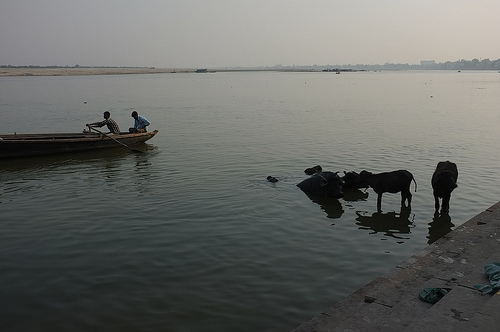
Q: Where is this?
A: This is at the lake.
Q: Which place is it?
A: It is a lake.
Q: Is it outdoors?
A: Yes, it is outdoors.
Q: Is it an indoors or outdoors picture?
A: It is outdoors.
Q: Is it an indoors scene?
A: No, it is outdoors.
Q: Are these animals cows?
A: Yes, all the animals are cows.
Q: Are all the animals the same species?
A: Yes, all the animals are cows.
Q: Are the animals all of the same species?
A: Yes, all the animals are cows.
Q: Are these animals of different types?
A: No, all the animals are cows.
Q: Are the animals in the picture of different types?
A: No, all the animals are cows.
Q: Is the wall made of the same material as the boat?
A: No, the wall is made of cement and the boat is made of wood.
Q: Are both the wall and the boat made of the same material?
A: No, the wall is made of cement and the boat is made of wood.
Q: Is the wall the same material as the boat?
A: No, the wall is made of cement and the boat is made of wood.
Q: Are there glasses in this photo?
A: No, there are no glasses.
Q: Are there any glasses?
A: No, there are no glasses.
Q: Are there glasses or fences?
A: No, there are no glasses or fences.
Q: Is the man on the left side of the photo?
A: Yes, the man is on the left of the image.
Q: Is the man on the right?
A: No, the man is on the left of the image.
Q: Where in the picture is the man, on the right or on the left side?
A: The man is on the left of the image.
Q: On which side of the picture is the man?
A: The man is on the left of the image.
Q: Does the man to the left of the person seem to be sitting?
A: Yes, the man is sitting.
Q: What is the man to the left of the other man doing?
A: The man is sitting.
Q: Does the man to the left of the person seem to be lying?
A: No, the man is sitting.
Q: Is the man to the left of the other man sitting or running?
A: The man is sitting.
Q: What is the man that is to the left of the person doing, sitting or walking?
A: The man is sitting.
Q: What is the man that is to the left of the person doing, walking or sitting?
A: The man is sitting.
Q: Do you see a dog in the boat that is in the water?
A: No, there is a man in the boat.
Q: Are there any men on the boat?
A: Yes, there is a man on the boat.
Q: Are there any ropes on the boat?
A: No, there is a man on the boat.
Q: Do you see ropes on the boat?
A: No, there is a man on the boat.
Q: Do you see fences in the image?
A: No, there are no fences.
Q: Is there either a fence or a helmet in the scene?
A: No, there are no fences or helmets.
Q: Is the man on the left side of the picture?
A: Yes, the man is on the left of the image.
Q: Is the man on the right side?
A: No, the man is on the left of the image.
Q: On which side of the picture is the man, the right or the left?
A: The man is on the left of the image.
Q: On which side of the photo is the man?
A: The man is on the left of the image.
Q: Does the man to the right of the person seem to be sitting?
A: Yes, the man is sitting.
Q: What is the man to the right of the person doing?
A: The man is sitting.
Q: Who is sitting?
A: The man is sitting.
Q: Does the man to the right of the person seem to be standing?
A: No, the man is sitting.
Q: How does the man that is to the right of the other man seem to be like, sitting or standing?
A: The man is sitting.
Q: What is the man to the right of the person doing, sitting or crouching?
A: The man is sitting.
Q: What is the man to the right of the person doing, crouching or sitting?
A: The man is sitting.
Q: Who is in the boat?
A: The man is in the boat.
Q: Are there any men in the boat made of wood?
A: Yes, there is a man in the boat.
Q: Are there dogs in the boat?
A: No, there is a man in the boat.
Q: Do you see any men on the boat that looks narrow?
A: Yes, there is a man on the boat.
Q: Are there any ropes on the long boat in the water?
A: No, there is a man on the boat.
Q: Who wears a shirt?
A: The man wears a shirt.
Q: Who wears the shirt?
A: The man wears a shirt.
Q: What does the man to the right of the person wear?
A: The man wears a shirt.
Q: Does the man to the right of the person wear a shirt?
A: Yes, the man wears a shirt.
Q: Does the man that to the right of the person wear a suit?
A: No, the man wears a shirt.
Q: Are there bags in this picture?
A: No, there are no bags.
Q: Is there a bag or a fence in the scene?
A: No, there are no bags or fences.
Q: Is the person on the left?
A: Yes, the person is on the left of the image.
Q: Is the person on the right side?
A: No, the person is on the left of the image.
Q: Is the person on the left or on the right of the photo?
A: The person is on the left of the image.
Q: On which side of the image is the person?
A: The person is on the left of the image.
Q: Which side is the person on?
A: The person is on the left of the image.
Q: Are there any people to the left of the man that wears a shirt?
A: Yes, there is a person to the left of the man.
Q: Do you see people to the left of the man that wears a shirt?
A: Yes, there is a person to the left of the man.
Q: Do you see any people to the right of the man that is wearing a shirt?
A: No, the person is to the left of the man.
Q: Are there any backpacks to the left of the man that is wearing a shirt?
A: No, there is a person to the left of the man.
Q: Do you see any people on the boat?
A: Yes, there is a person on the boat.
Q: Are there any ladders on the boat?
A: No, there is a person on the boat.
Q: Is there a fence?
A: No, there are no fences.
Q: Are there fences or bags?
A: No, there are no fences or bags.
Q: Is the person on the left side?
A: Yes, the person is on the left of the image.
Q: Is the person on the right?
A: No, the person is on the left of the image.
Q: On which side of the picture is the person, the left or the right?
A: The person is on the left of the image.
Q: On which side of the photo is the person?
A: The person is on the left of the image.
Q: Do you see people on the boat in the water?
A: Yes, there is a person on the boat.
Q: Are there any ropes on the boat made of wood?
A: No, there is a person on the boat.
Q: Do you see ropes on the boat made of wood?
A: No, there is a person on the boat.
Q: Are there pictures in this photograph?
A: No, there are no pictures.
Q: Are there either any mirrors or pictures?
A: No, there are no pictures or mirrors.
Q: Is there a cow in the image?
A: Yes, there is a cow.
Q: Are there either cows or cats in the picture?
A: Yes, there is a cow.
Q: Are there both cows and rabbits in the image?
A: No, there is a cow but no rabbits.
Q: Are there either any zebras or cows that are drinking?
A: Yes, the cow is drinking.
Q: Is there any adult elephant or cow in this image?
A: Yes, there is an adult cow.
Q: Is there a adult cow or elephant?
A: Yes, there is an adult cow.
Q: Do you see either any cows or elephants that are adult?
A: Yes, the cow is adult.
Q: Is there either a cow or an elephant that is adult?
A: Yes, the cow is adult.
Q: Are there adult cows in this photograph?
A: Yes, there is an adult cow.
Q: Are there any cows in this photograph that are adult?
A: Yes, there is a cow that is adult.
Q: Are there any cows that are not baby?
A: Yes, there is a adult cow.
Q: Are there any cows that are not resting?
A: Yes, there is a cow that is drinking.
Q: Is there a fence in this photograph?
A: No, there are no fences.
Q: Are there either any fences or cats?
A: No, there are no fences or cats.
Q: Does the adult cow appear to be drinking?
A: Yes, the cow is drinking.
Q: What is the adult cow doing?
A: The cow is drinking.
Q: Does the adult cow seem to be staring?
A: No, the cow is drinking.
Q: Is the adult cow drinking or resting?
A: The cow is drinking.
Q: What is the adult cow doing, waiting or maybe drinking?
A: The cow is drinking.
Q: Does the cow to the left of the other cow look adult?
A: Yes, the cow is adult.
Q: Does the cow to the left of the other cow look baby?
A: No, the cow is adult.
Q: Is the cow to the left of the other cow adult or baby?
A: The cow is adult.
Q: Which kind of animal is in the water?
A: The animal is a cow.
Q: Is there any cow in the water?
A: Yes, there is a cow in the water.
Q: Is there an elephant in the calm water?
A: No, there is a cow in the water.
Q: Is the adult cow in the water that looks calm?
A: Yes, the cow is in the water.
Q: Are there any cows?
A: Yes, there is a cow.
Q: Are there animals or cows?
A: Yes, there is a cow.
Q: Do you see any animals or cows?
A: Yes, there is a cow.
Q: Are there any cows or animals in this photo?
A: Yes, there is a cow.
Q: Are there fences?
A: No, there are no fences.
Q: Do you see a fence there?
A: No, there are no fences.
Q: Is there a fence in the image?
A: No, there are no fences.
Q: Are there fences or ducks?
A: No, there are no fences or ducks.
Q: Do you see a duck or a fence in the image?
A: No, there are no fences or ducks.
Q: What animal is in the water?
A: The animal is a cow.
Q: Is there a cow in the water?
A: Yes, there is a cow in the water.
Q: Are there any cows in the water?
A: Yes, there is a cow in the water.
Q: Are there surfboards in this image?
A: No, there are no surfboards.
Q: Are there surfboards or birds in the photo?
A: No, there are no surfboards or birds.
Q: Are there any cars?
A: No, there are no cars.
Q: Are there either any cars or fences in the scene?
A: No, there are no cars or fences.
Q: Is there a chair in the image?
A: No, there are no chairs.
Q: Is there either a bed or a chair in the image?
A: No, there are no chairs or beds.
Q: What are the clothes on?
A: The clothes are on the wall.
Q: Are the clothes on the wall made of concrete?
A: Yes, the clothes are on the wall.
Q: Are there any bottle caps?
A: No, there are no bottle caps.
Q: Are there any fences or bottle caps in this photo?
A: No, there are no bottle caps or fences.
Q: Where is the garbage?
A: The garbage is in the water.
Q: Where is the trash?
A: The garbage is in the water.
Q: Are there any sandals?
A: Yes, there are sandals.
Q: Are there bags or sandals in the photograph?
A: Yes, there are sandals.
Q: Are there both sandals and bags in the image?
A: No, there are sandals but no bags.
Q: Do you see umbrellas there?
A: No, there are no umbrellas.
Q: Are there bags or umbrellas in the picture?
A: No, there are no umbrellas or bags.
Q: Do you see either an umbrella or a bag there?
A: No, there are no umbrellas or bags.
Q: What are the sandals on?
A: The sandals are on the wall.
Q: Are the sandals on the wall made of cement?
A: Yes, the sandals are on the wall.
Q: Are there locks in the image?
A: No, there are no locks.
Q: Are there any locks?
A: No, there are no locks.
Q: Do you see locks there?
A: No, there are no locks.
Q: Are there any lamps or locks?
A: No, there are no locks or lamps.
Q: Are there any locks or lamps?
A: No, there are no locks or lamps.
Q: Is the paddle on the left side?
A: Yes, the paddle is on the left of the image.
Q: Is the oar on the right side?
A: No, the oar is on the left of the image.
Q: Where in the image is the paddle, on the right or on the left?
A: The paddle is on the left of the image.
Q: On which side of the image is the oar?
A: The oar is on the left of the image.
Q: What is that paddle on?
A: The paddle is on the boat.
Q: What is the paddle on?
A: The paddle is on the boat.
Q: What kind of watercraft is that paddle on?
A: The paddle is on the boat.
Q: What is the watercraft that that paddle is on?
A: The watercraft is a boat.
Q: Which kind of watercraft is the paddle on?
A: The paddle is on the boat.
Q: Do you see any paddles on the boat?
A: Yes, there is a paddle on the boat.